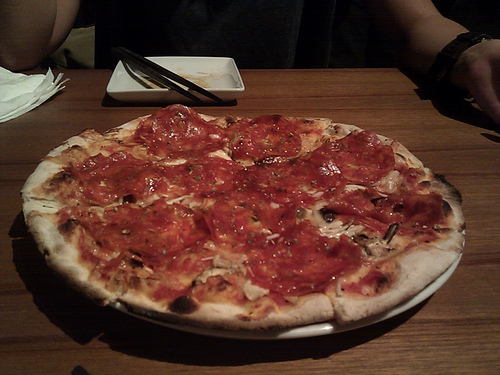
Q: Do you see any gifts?
A: No, there are no gifts.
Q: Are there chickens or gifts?
A: No, there are no gifts or chickens.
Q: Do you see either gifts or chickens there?
A: No, there are no gifts or chickens.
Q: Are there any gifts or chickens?
A: No, there are no gifts or chickens.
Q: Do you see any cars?
A: No, there are no cars.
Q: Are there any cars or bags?
A: No, there are no cars or bags.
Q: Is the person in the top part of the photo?
A: Yes, the person is in the top of the image.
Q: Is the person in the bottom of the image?
A: No, the person is in the top of the image.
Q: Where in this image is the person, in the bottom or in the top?
A: The person is in the top of the image.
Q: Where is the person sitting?
A: The person is sitting at the table.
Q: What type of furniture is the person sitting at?
A: The person is sitting at the table.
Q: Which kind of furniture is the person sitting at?
A: The person is sitting at the table.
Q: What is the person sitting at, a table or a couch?
A: The person is sitting at a table.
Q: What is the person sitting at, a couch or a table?
A: The person is sitting at a table.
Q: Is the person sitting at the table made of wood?
A: Yes, the person is sitting at the table.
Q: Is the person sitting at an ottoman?
A: No, the person is sitting at the table.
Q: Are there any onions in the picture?
A: No, there are no onions.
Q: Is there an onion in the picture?
A: No, there are no onions.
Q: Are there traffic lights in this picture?
A: No, there are no traffic lights.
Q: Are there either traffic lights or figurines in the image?
A: No, there are no traffic lights or figurines.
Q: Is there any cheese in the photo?
A: Yes, there is cheese.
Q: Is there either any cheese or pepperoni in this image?
A: Yes, there is cheese.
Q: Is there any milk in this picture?
A: No, there is no milk.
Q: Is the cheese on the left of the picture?
A: Yes, the cheese is on the left of the image.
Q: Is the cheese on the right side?
A: No, the cheese is on the left of the image.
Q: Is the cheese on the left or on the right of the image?
A: The cheese is on the left of the image.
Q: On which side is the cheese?
A: The cheese is on the left of the image.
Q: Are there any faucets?
A: No, there are no faucets.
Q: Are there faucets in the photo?
A: No, there are no faucets.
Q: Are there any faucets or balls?
A: No, there are no faucets or balls.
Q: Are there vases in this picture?
A: No, there are no vases.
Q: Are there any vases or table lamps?
A: No, there are no vases or table lamps.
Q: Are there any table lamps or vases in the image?
A: No, there are no vases or table lamps.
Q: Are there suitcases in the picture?
A: No, there are no suitcases.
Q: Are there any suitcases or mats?
A: No, there are no suitcases or mats.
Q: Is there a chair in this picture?
A: No, there are no chairs.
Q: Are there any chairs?
A: No, there are no chairs.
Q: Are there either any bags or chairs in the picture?
A: No, there are no chairs or bags.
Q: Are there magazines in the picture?
A: No, there are no magazines.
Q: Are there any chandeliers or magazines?
A: No, there are no magazines or chandeliers.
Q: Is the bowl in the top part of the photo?
A: Yes, the bowl is in the top of the image.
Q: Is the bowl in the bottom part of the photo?
A: No, the bowl is in the top of the image.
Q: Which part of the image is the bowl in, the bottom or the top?
A: The bowl is in the top of the image.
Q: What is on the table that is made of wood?
A: The bowl is on the table.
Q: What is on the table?
A: The bowl is on the table.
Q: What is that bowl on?
A: The bowl is on the table.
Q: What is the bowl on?
A: The bowl is on the table.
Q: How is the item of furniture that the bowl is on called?
A: The piece of furniture is a table.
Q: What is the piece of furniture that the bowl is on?
A: The piece of furniture is a table.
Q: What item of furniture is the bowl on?
A: The bowl is on the table.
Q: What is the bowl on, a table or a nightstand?
A: The bowl is on a table.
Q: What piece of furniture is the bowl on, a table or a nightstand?
A: The bowl is on a table.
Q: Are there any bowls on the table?
A: Yes, there is a bowl on the table.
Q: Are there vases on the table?
A: No, there is a bowl on the table.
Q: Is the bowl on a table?
A: Yes, the bowl is on a table.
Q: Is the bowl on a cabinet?
A: No, the bowl is on a table.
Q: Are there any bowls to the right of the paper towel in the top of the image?
A: Yes, there is a bowl to the right of the paper towel.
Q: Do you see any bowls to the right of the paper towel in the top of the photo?
A: Yes, there is a bowl to the right of the paper towel.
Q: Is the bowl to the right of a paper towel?
A: Yes, the bowl is to the right of a paper towel.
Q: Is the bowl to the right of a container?
A: No, the bowl is to the right of a paper towel.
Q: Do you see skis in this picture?
A: No, there are no skis.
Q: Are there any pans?
A: No, there are no pans.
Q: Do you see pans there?
A: No, there are no pans.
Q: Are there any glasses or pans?
A: No, there are no pans or glasses.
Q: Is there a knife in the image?
A: No, there are no knives.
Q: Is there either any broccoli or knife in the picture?
A: No, there are no knives or broccoli.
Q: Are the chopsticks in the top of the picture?
A: Yes, the chopsticks are in the top of the image.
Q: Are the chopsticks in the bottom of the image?
A: No, the chopsticks are in the top of the image.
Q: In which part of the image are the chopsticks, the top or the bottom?
A: The chopsticks are in the top of the image.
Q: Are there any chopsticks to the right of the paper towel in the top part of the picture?
A: Yes, there are chopsticks to the right of the paper towel.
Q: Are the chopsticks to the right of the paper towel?
A: Yes, the chopsticks are to the right of the paper towel.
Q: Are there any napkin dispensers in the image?
A: No, there are no napkin dispensers.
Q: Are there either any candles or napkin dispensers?
A: No, there are no napkin dispensers or candles.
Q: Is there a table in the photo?
A: Yes, there is a table.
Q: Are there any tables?
A: Yes, there is a table.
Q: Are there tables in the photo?
A: Yes, there is a table.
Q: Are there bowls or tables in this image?
A: Yes, there is a table.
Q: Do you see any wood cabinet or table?
A: Yes, there is a wood table.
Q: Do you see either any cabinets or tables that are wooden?
A: Yes, the table is wooden.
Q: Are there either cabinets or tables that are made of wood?
A: Yes, the table is made of wood.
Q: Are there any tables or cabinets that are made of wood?
A: Yes, the table is made of wood.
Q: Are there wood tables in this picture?
A: Yes, there is a wood table.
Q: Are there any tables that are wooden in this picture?
A: Yes, there is a wood table.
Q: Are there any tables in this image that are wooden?
A: Yes, there is a table that is wooden.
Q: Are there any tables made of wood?
A: Yes, there is a table that is made of wood.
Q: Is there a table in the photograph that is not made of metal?
A: Yes, there is a table that is made of wood.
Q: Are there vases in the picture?
A: No, there are no vases.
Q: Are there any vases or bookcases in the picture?
A: No, there are no vases or bookcases.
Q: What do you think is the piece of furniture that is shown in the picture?
A: The piece of furniture is a table.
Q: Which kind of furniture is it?
A: The piece of furniture is a table.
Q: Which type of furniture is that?
A: This is a table.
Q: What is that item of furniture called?
A: This is a table.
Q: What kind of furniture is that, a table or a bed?
A: This is a table.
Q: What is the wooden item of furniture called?
A: The piece of furniture is a table.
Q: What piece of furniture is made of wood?
A: The piece of furniture is a table.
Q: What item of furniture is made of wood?
A: The piece of furniture is a table.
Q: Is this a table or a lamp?
A: This is a table.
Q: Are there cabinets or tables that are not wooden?
A: No, there is a table but it is wooden.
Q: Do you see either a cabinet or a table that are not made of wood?
A: No, there is a table but it is made of wood.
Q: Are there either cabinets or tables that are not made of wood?
A: No, there is a table but it is made of wood.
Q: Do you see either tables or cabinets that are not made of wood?
A: No, there is a table but it is made of wood.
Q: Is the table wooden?
A: Yes, the table is wooden.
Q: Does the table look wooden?
A: Yes, the table is wooden.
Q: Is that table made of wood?
A: Yes, the table is made of wood.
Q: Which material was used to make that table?
A: The table is made of wood.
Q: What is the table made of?
A: The table is made of wood.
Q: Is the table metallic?
A: No, the table is wooden.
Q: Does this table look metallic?
A: No, the table is wooden.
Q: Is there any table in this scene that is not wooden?
A: No, there is a table but it is wooden.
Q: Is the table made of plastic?
A: No, the table is made of wood.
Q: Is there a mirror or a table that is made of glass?
A: No, there is a table but it is made of wood.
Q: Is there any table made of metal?
A: No, there is a table but it is made of wood.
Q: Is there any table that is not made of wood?
A: No, there is a table but it is made of wood.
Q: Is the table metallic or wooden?
A: The table is wooden.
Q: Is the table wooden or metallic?
A: The table is wooden.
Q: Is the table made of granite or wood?
A: The table is made of wood.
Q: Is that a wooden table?
A: Yes, that is a wooden table.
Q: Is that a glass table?
A: No, that is a wooden table.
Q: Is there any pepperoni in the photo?
A: Yes, there is pepperoni.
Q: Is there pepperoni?
A: Yes, there is pepperoni.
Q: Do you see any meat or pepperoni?
A: Yes, there is pepperoni.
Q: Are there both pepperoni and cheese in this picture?
A: Yes, there are both pepperoni and cheese.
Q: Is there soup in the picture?
A: No, there is no soup.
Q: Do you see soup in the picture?
A: No, there is no soup.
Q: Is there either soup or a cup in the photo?
A: No, there are no soup or cups.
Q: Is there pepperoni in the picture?
A: Yes, there is pepperoni.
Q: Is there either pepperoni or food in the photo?
A: Yes, there is pepperoni.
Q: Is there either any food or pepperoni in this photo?
A: Yes, there is pepperoni.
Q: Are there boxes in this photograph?
A: No, there are no boxes.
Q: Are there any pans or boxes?
A: No, there are no boxes or pans.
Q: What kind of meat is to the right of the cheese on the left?
A: The meat is pepperoni.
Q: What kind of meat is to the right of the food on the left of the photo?
A: The meat is pepperoni.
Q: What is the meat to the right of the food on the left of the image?
A: The meat is pepperoni.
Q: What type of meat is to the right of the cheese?
A: The meat is pepperoni.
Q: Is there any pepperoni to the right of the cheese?
A: Yes, there is pepperoni to the right of the cheese.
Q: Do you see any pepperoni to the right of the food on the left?
A: Yes, there is pepperoni to the right of the cheese.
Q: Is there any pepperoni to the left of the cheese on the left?
A: No, the pepperoni is to the right of the cheese.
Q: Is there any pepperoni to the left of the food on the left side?
A: No, the pepperoni is to the right of the cheese.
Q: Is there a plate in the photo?
A: Yes, there is a plate.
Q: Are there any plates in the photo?
A: Yes, there is a plate.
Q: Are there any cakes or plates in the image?
A: Yes, there is a plate.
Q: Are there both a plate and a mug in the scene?
A: No, there is a plate but no mugs.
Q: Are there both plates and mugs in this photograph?
A: No, there is a plate but no mugs.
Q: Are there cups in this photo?
A: No, there are no cups.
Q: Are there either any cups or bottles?
A: No, there are no cups or bottles.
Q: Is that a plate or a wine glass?
A: That is a plate.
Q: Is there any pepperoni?
A: Yes, there is pepperoni.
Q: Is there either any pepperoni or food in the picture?
A: Yes, there is pepperoni.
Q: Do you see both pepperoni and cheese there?
A: Yes, there are both pepperoni and cheese.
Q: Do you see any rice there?
A: No, there is no rice.